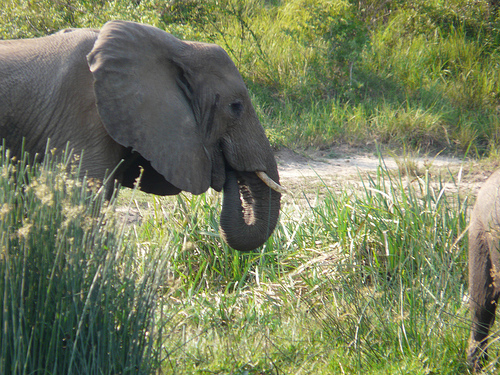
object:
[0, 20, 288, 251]
elephant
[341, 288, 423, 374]
grass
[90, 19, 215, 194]
ears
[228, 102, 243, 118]
eye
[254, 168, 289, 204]
tusks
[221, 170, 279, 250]
trunk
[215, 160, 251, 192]
mouth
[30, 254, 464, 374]
ground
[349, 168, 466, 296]
weeds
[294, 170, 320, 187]
dirt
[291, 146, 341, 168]
twig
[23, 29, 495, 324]
photo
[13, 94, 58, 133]
skin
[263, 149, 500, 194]
path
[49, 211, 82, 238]
buds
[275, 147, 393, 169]
sand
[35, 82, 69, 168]
lines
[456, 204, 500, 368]
leg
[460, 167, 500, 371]
elephant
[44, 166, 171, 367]
shrub